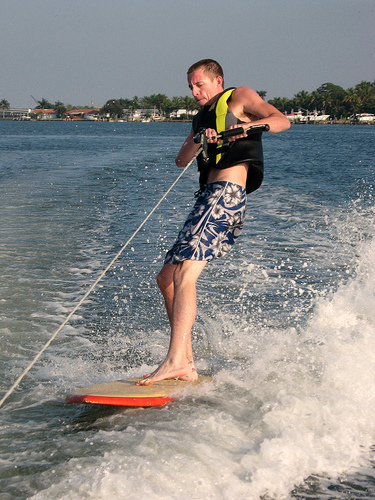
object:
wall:
[35, 112, 55, 120]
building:
[28, 108, 56, 118]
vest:
[179, 105, 269, 175]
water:
[0, 117, 374, 494]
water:
[34, 177, 68, 206]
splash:
[311, 183, 373, 258]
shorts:
[163, 179, 254, 271]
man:
[135, 55, 292, 390]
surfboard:
[59, 369, 220, 419]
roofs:
[28, 104, 93, 114]